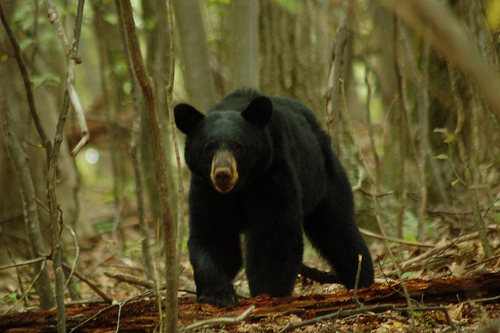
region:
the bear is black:
[129, 47, 412, 305]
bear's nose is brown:
[196, 143, 249, 202]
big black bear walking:
[116, 94, 370, 289]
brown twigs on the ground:
[153, 275, 488, 332]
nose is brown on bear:
[206, 138, 238, 221]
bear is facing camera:
[168, 96, 277, 238]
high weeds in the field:
[13, 95, 113, 322]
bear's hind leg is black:
[311, 176, 402, 286]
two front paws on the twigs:
[203, 290, 306, 310]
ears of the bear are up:
[153, 95, 273, 128]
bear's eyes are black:
[168, 129, 252, 159]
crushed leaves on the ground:
[371, 226, 473, 285]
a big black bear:
[165, 88, 375, 308]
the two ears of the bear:
[175, 97, 272, 129]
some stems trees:
[7, 105, 182, 305]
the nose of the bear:
[213, 167, 230, 186]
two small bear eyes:
[205, 137, 241, 152]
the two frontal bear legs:
[188, 218, 300, 303]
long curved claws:
[198, 290, 239, 307]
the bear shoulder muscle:
[210, 87, 260, 110]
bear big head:
[171, 104, 269, 191]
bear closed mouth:
[208, 181, 240, 192]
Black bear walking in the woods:
[7, 3, 493, 330]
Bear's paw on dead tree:
[195, 280, 241, 330]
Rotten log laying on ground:
[1, 273, 498, 329]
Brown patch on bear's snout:
[209, 148, 239, 192]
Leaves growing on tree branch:
[430, 123, 498, 210]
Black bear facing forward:
[171, 86, 376, 303]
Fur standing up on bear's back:
[230, 85, 260, 97]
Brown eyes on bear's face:
[202, 138, 244, 153]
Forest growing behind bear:
[6, 3, 499, 328]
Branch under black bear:
[299, 260, 339, 285]